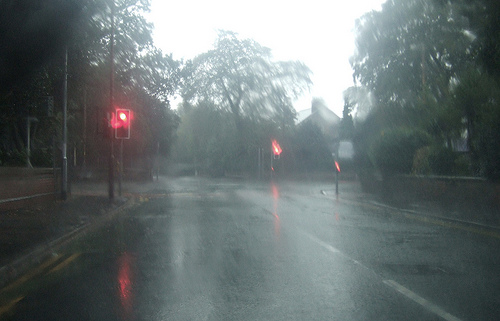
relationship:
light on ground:
[116, 249, 134, 303] [80, 202, 463, 319]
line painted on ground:
[279, 205, 447, 319] [154, 189, 494, 319]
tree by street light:
[173, 26, 315, 198] [265, 138, 286, 164]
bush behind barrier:
[369, 127, 500, 178] [372, 166, 495, 225]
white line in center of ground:
[274, 196, 452, 318] [0, 178, 500, 319]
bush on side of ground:
[363, 127, 423, 175] [0, 178, 500, 319]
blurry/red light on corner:
[111, 108, 131, 130] [54, 171, 143, 244]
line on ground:
[299, 227, 463, 321] [0, 178, 500, 319]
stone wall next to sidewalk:
[364, 165, 499, 219] [345, 184, 497, 241]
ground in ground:
[0, 178, 500, 319] [0, 178, 500, 319]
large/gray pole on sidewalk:
[56, 40, 70, 204] [1, 180, 131, 273]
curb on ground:
[9, 197, 139, 302] [0, 178, 500, 319]